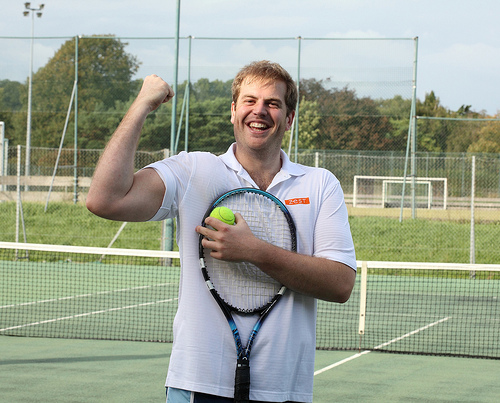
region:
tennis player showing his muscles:
[76, 51, 363, 398]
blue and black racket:
[198, 184, 306, 401]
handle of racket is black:
[224, 350, 256, 401]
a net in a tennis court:
[5, 236, 497, 355]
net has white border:
[1, 235, 499, 367]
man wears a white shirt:
[88, 54, 366, 397]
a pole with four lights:
[17, 2, 45, 177]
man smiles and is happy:
[170, 45, 345, 210]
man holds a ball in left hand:
[80, 45, 371, 366]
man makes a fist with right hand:
[88, 40, 243, 164]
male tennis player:
[132, 62, 326, 383]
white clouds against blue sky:
[5, 15, 53, 66]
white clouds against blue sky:
[67, 11, 112, 36]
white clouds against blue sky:
[134, 19, 159, 40]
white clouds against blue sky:
[162, 12, 204, 44]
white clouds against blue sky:
[147, 22, 231, 73]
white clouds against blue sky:
[205, 8, 270, 50]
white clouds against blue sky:
[277, 15, 345, 56]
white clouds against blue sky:
[331, 26, 392, 77]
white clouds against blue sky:
[397, 12, 448, 74]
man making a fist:
[86, 55, 361, 396]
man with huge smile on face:
[227, 60, 293, 165]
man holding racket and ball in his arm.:
[195, 180, 356, 391]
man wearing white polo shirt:
[150, 130, 350, 396]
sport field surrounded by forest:
[10, 38, 491, 185]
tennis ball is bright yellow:
[200, 200, 245, 235]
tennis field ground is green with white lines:
[1, 261, 481, 392]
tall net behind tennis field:
[1, 33, 436, 219]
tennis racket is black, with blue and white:
[198, 183, 309, 399]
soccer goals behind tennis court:
[349, 167, 459, 215]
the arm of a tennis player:
[79, 103, 206, 225]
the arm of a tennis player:
[254, 168, 354, 298]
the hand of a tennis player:
[136, 73, 170, 107]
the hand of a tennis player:
[200, 211, 246, 261]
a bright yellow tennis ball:
[208, 208, 238, 230]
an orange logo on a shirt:
[283, 193, 307, 206]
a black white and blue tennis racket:
[196, 181, 308, 401]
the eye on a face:
[243, 93, 256, 110]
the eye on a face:
[267, 98, 280, 110]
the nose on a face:
[250, 96, 266, 115]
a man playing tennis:
[59, 18, 350, 375]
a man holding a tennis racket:
[108, 34, 404, 362]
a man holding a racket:
[97, 18, 422, 398]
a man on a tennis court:
[100, 16, 490, 397]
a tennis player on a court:
[30, 37, 397, 389]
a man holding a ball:
[144, 69, 384, 383]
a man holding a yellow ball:
[127, 33, 454, 400]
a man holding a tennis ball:
[150, 81, 378, 393]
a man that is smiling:
[179, 7, 301, 187]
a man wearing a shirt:
[157, 58, 424, 366]